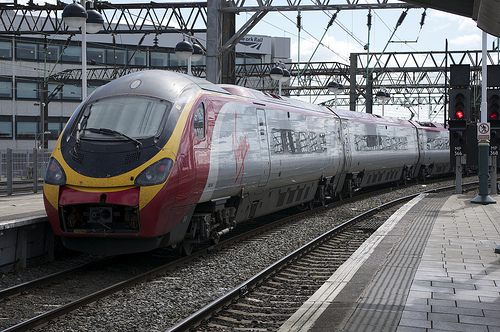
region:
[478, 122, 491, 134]
No walking sign on a post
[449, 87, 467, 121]
Right light on a street sign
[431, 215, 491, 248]
Grey bricks on a sidewalk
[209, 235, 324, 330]
Tracks on a train rail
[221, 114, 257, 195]
Red VIRGIN sign on a train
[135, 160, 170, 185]
Headlight on a train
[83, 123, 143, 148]
Wiper blade on a train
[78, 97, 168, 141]
Windshield on a train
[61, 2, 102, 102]
Lights on a light post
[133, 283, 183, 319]
Gravel on a train track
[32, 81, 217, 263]
the front of the train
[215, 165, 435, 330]
train tracks in the ground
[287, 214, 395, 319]
the curb of the train tracks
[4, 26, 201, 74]
windows of a building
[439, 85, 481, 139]
a traffic light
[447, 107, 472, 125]
a red light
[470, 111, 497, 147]
a red and white traffic sign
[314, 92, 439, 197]
a train car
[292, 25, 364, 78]
white clouds in the sky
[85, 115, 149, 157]
windshield wiper of the train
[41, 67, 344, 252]
a silver train engine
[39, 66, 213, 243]
red yellow and black train engine front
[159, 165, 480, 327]
set of railroad tracks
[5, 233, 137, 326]
set of railroad tracks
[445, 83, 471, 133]
an electric train traffic light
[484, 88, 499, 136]
an electric train traffic light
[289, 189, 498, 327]
train boarding platform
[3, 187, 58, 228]
a train boarding platform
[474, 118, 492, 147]
a no entry sign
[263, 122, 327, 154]
a long train window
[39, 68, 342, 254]
a silver red and yellow train engine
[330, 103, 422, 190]
a red and silver train car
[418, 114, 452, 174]
a red and silver train car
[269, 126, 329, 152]
train passenger windows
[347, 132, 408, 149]
train passenger windows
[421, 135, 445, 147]
train passenger windows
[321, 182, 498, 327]
a brick paved train boarding platform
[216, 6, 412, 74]
a set of overhead power lines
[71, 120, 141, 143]
a large train windshield wiper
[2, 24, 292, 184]
a large white building in distance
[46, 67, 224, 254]
The front is red and yellow.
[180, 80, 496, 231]
The back is grey.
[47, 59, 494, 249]
The train is long.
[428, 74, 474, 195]
The light is red.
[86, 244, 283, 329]
The track is clear.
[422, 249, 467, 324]
The ground is grey.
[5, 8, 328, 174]
The building is white.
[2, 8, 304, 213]
The building has lots of windows.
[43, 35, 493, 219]
The train is stopped.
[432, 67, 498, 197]
The sign is white and red.